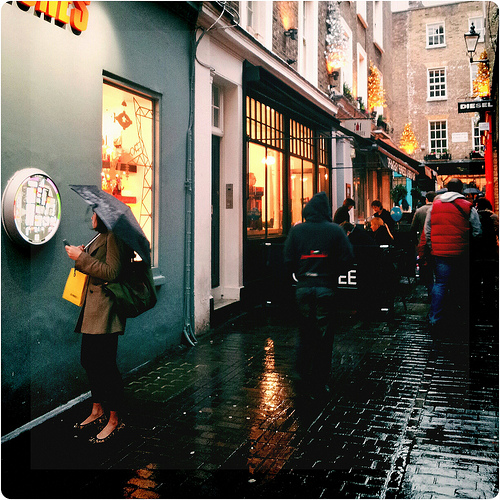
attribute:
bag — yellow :
[58, 267, 88, 306]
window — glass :
[429, 116, 449, 156]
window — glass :
[419, 63, 448, 103]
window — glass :
[422, 18, 446, 50]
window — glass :
[465, 14, 485, 45]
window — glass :
[466, 113, 488, 155]